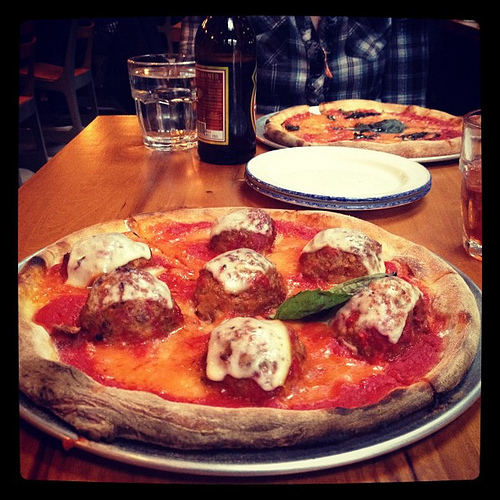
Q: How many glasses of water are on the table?
A: One.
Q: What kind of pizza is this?
A: Meatball with cheese pizza.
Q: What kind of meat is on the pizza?
A: Meatballs.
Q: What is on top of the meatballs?
A: Cheese.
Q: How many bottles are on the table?
A: One.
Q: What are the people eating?
A: Pizza.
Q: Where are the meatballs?
A: On the pizza.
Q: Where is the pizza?
A: On a tray.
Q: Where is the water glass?
A: Next to the beer.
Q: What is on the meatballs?
A: Cheese.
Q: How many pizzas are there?
A: 2.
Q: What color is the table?
A: Brown.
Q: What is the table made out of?
A: Wood.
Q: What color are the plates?
A: White.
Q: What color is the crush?
A: Brown.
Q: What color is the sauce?
A: Red.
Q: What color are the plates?
A: White and blue.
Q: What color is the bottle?
A: Black.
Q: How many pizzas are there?
A: Two.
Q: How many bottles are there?
A: One.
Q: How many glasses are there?
A: Two.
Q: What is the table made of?
A: Wood.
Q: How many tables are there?
A: One.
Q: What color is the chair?
A: Brown.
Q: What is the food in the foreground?
A: Pizza.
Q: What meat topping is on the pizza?
A: Meatballs.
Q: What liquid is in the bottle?
A: Beer.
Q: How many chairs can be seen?
A: 2.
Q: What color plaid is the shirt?
A: Blue.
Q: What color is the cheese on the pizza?
A: Orange.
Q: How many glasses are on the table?
A: 2.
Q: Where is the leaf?
A: On the pizza.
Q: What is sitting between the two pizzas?
A: Plates.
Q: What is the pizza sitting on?
A: A pan.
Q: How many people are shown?
A: 1.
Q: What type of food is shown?
A: Pizza.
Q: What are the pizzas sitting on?
A: Plate.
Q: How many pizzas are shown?
A: 2.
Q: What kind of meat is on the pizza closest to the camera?
A: Meatballs.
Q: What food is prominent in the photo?
A: Pizza.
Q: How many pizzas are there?
A: Two.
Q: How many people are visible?
A: One.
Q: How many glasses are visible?
A: Two.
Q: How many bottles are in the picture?
A: One.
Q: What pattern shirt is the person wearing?
A: Plaid.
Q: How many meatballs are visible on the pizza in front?
A: Seven.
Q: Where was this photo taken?
A: A restaurant.